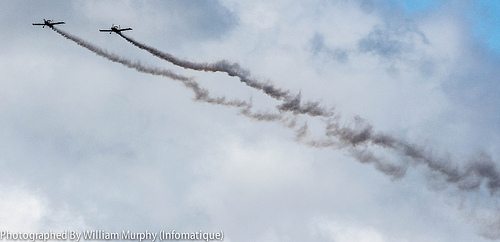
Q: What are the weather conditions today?
A: It is cloudy.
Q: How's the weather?
A: It is cloudy.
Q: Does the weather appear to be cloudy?
A: Yes, it is cloudy.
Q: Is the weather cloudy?
A: Yes, it is cloudy.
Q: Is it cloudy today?
A: Yes, it is cloudy.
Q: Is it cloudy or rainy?
A: It is cloudy.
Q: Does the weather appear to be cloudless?
A: No, it is cloudy.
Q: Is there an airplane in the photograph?
A: Yes, there is an airplane.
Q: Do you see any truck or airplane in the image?
A: Yes, there is an airplane.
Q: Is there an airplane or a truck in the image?
A: Yes, there is an airplane.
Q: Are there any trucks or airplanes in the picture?
A: Yes, there is an airplane.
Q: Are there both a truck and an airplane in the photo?
A: No, there is an airplane but no trucks.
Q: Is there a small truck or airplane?
A: Yes, there is a small airplane.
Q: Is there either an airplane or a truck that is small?
A: Yes, the airplane is small.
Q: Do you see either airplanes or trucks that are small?
A: Yes, the airplane is small.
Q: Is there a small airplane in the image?
A: Yes, there is a small airplane.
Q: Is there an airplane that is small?
A: Yes, there is an airplane that is small.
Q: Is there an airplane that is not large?
A: Yes, there is a small airplane.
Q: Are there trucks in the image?
A: No, there are no trucks.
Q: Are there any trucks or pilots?
A: No, there are no trucks or pilots.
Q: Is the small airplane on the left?
A: Yes, the plane is on the left of the image.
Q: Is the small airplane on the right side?
A: No, the airplane is on the left of the image.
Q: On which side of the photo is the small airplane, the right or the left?
A: The airplane is on the left of the image.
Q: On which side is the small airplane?
A: The plane is on the left of the image.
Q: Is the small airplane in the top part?
A: Yes, the airplane is in the top of the image.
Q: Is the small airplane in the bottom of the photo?
A: No, the plane is in the top of the image.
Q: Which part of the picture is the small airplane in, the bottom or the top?
A: The plane is in the top of the image.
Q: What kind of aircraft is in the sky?
A: The aircraft is an airplane.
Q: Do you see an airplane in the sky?
A: Yes, there is an airplane in the sky.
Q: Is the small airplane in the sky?
A: Yes, the plane is in the sky.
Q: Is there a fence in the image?
A: No, there are no fences.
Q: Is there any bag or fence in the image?
A: No, there are no fences or bags.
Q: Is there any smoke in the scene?
A: Yes, there is smoke.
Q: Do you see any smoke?
A: Yes, there is smoke.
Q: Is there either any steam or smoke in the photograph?
A: Yes, there is smoke.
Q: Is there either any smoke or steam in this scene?
A: Yes, there is smoke.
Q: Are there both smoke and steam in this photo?
A: No, there is smoke but no steam.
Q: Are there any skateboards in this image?
A: No, there are no skateboards.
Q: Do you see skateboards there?
A: No, there are no skateboards.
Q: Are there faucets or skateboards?
A: No, there are no skateboards or faucets.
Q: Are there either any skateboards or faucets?
A: No, there are no skateboards or faucets.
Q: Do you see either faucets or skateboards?
A: No, there are no skateboards or faucets.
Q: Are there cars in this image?
A: No, there are no cars.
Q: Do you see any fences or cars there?
A: No, there are no cars or fences.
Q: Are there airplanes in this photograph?
A: Yes, there are airplanes.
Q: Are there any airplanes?
A: Yes, there are airplanes.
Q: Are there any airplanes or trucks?
A: Yes, there are airplanes.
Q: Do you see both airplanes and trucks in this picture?
A: No, there are airplanes but no trucks.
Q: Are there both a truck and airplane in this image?
A: No, there are airplanes but no trucks.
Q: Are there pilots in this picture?
A: No, there are no pilots.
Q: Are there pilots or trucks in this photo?
A: No, there are no pilots or trucks.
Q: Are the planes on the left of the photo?
A: Yes, the planes are on the left of the image.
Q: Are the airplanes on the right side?
A: No, the airplanes are on the left of the image.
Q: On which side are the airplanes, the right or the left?
A: The airplanes are on the left of the image.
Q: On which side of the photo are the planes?
A: The planes are on the left of the image.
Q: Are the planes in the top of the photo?
A: Yes, the planes are in the top of the image.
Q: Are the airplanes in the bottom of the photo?
A: No, the airplanes are in the top of the image.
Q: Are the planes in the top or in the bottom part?
A: The planes are in the top of the image.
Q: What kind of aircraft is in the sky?
A: The aircraft is airplanes.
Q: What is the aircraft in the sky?
A: The aircraft is airplanes.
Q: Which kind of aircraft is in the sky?
A: The aircraft is airplanes.